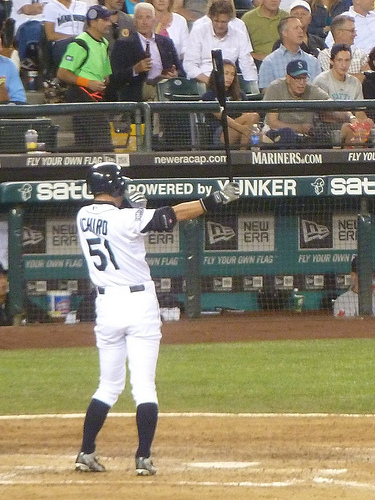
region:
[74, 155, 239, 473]
Baseball player in a game.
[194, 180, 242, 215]
Navy and gray glove on hand.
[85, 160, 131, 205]
Navy helmet on head.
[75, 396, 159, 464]
Navy socks on man.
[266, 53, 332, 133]
Man wearing glasses.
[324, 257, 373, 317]
Player sitting in dugout.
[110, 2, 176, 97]
Man holding a beer.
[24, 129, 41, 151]
Drink cup on ledge.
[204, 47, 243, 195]
Black baseball bat in hand.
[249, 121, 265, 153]
Bottle of water on ledge.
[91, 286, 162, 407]
a pair of white pants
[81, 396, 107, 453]
a long black sock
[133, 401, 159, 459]
a long black sock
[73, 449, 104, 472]
a grey and white cleated shoe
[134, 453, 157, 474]
a grey and white cleated shoe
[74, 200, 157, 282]
a white baseball jersey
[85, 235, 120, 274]
printed player number 51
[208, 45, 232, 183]
a black baseball bat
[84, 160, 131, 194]
a black baseball hat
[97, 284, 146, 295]
a men's black belt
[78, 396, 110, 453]
long black sock on batter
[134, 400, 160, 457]
long black sock of batter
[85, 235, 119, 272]
black number on back of jersey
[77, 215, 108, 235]
black name on back of jersey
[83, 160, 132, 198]
batter wearing black helmet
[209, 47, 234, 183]
batter holding black bat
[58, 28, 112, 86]
man in stands in green shirt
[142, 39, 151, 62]
man in suit jacket holding beer bottle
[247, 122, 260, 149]
water bottle sitting above dugout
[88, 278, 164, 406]
player wearing white pants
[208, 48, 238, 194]
A black baseball bat.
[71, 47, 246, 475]
A man holding up a baseball bat.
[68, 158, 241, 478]
A baseball player.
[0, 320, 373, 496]
A baseball field.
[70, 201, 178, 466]
A black and white baseball uniform.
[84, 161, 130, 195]
A dark colored helmet.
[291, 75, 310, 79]
A pair of glasses.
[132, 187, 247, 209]
Grey and black batting gloves.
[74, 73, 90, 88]
An orange armband.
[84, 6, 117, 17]
a blue ball cap.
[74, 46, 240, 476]
a baseball player swinging bat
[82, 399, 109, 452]
a long blue sock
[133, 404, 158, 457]
a long blue sock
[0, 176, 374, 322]
a green baseball dugout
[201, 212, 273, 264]
a New Era promotional advertisement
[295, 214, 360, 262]
a New Era promotional advertisement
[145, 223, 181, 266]
a New Era promotional advertisement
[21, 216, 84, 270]
a New Era promotional advertisement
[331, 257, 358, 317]
a baseball player in dugout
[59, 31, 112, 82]
a neon green t-shirt